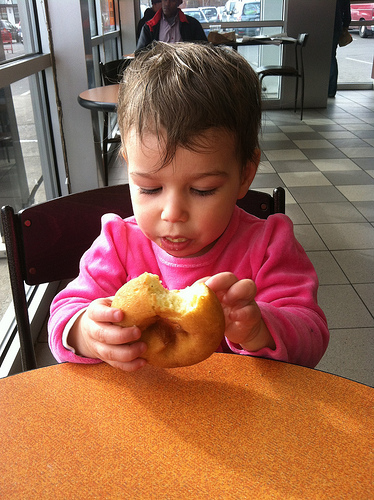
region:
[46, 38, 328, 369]
The child is eating a donut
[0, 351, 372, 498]
The table is orange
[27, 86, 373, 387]
The flooring is tile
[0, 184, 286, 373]
The chair is metal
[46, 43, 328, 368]
The child has on a pink shirt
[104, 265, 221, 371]
Donut is a cake donut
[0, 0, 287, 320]
Building has several large windows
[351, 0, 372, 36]
Large red vehicle in corner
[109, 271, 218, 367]
The donut is yellow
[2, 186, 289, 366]
The chair is black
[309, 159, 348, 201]
part of the floor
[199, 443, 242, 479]
surface of a table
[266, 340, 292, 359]
sleeve of a jumper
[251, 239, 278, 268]
part of a sweater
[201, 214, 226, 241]
cheek of a baby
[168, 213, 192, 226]
nose of a baby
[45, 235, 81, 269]
part of a chair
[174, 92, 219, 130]
hair of the baby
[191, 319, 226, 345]
part of a doughnut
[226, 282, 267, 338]
part of some fingers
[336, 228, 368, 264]
part of the floor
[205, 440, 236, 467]
part of a table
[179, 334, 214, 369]
part of a doughnut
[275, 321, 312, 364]
sleeve of a jumper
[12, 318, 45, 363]
part of a stand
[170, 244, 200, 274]
part of a collar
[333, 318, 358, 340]
part of a line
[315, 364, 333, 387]
edge of a table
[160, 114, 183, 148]
hair of a baby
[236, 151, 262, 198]
ear of the baby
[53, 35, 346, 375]
A little girl is eating a doughnut.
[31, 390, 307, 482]
The table is brownish orange.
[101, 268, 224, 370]
The doughnut is plane.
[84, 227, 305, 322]
The girl's shirt is pink.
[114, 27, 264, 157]
The girl has brown hair.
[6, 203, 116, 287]
The chair is brown.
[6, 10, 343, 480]
The picture was taken at a restaurant.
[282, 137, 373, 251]
The floor is tile covered.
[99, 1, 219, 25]
A man looking out the window.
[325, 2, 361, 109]
A person walking out the door.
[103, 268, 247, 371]
the doughnut is bitten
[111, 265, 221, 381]
this is a doughnut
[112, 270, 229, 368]
the doughnut is brown in color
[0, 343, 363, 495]
this is a table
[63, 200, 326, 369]
the kid is eating a doughnut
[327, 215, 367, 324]
this is the floor of the restaurant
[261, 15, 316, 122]
this is a chair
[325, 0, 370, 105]
this is the door of the hotel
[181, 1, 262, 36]
these are vehicles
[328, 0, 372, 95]
the man is holding something